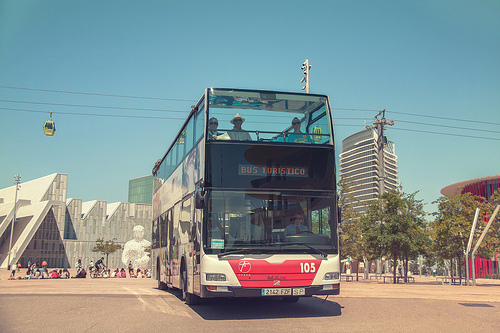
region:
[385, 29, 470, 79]
the clear blue sky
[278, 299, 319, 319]
a shadow under the bus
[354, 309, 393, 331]
the street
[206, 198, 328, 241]
a windshield on the bus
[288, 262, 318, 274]
a number on the bus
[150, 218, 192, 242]
windows on the bus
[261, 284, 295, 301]
a license plate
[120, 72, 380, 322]
A bus in the foreground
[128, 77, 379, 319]
A double decker bus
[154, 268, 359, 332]
Bus is casting a shadow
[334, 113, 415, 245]
A building in the background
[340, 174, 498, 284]
small trees in the background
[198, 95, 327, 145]
People on the top of the bus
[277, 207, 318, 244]
Bus driver in the foreground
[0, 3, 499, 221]
The sky is clear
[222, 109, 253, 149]
Man is wearing a hat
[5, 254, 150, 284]
A group of people in the background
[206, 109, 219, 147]
this is a person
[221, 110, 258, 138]
this is a person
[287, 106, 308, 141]
this is a person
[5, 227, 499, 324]
this is a road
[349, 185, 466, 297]
these are trees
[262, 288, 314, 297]
this is a number plate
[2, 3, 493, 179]
this is the sky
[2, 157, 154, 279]
these are buldings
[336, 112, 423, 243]
this is a bulding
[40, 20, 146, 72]
this is the sky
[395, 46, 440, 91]
the sky is blue in color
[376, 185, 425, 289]
this is a tree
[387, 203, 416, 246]
the leaves are green in color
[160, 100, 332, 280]
this is a bus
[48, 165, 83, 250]
this is a building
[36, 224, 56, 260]
this is the wall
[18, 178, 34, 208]
the wall is white in color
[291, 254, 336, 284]
this is a writing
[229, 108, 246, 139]
this is a man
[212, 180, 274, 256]
window of a bus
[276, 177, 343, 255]
window of a bus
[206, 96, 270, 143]
window of a bus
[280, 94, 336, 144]
window of a bus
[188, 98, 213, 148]
window of a bus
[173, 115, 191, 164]
window of a bus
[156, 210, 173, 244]
window of a bus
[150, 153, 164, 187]
window of a bus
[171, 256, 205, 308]
tire of a bus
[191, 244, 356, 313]
bumper of a bus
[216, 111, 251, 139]
man sitting inside bus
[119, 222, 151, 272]
large white sculpture behind bus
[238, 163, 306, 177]
LED display located on on bus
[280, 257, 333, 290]
number on the bus